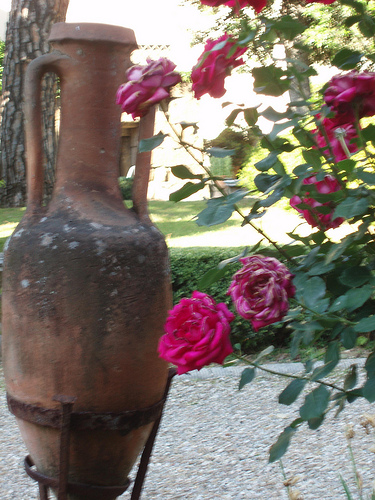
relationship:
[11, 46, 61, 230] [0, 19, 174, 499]
handle attaches pot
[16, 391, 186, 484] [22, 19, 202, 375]
base holds pot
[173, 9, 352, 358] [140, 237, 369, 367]
flowers grows from bush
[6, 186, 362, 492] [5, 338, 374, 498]
ground beside gravel